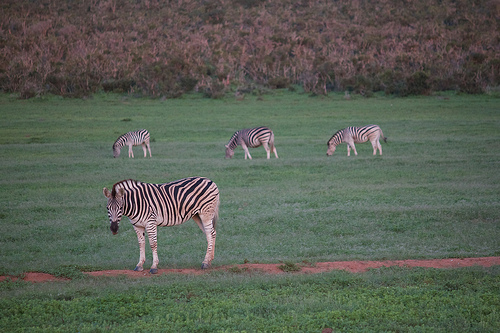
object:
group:
[96, 90, 390, 285]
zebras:
[220, 125, 280, 161]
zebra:
[101, 174, 219, 273]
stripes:
[140, 183, 198, 216]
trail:
[0, 255, 499, 283]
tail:
[379, 127, 387, 145]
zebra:
[324, 123, 390, 158]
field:
[0, 86, 499, 333]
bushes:
[0, 0, 499, 101]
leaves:
[406, 70, 435, 97]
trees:
[0, 0, 499, 100]